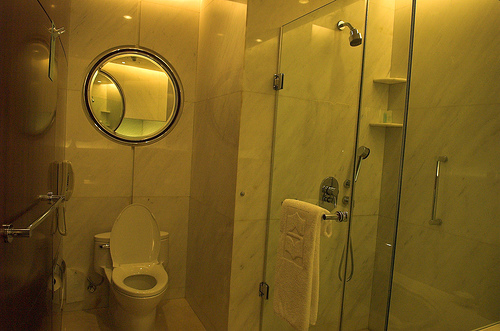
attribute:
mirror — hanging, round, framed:
[87, 51, 180, 141]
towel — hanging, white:
[274, 199, 334, 330]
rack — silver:
[281, 197, 347, 222]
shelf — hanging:
[371, 76, 407, 87]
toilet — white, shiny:
[94, 202, 172, 330]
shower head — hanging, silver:
[338, 19, 362, 45]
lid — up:
[109, 205, 161, 266]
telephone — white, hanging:
[56, 159, 76, 236]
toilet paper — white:
[51, 275, 62, 292]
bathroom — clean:
[2, 1, 498, 328]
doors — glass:
[257, 1, 499, 330]